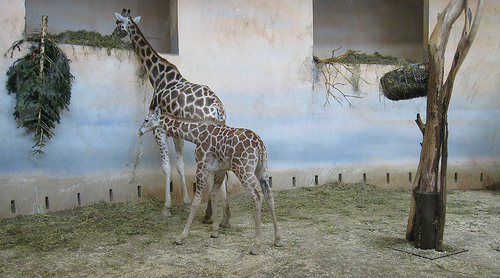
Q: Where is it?
A: This is at the zoo.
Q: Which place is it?
A: It is a zoo.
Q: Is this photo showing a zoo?
A: Yes, it is showing a zoo.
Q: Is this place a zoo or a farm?
A: It is a zoo.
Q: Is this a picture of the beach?
A: No, the picture is showing the zoo.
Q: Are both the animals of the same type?
A: Yes, all the animals are giraffes.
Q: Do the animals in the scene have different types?
A: No, all the animals are giraffes.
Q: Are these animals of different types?
A: No, all the animals are giraffes.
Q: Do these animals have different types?
A: No, all the animals are giraffes.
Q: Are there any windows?
A: Yes, there is a window.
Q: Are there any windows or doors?
A: Yes, there is a window.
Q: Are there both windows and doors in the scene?
A: No, there is a window but no doors.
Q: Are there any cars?
A: No, there are no cars.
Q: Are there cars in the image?
A: No, there are no cars.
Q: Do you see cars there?
A: No, there are no cars.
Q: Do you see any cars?
A: No, there are no cars.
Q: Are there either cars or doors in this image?
A: No, there are no cars or doors.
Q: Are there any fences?
A: No, there are no fences.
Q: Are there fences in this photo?
A: No, there are no fences.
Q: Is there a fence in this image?
A: No, there are no fences.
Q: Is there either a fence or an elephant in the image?
A: No, there are no fences or elephants.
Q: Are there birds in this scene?
A: No, there are no birds.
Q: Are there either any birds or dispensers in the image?
A: No, there are no birds or dispensers.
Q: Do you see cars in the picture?
A: No, there are no cars.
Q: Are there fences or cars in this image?
A: No, there are no cars or fences.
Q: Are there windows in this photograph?
A: Yes, there is a window.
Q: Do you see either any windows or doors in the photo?
A: Yes, there is a window.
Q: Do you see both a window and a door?
A: No, there is a window but no doors.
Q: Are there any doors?
A: No, there are no doors.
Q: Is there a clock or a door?
A: No, there are no doors or clocks.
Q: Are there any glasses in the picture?
A: No, there are no glasses.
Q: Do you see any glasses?
A: No, there are no glasses.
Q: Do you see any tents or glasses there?
A: No, there are no glasses or tents.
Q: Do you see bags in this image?
A: No, there are no bags.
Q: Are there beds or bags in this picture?
A: No, there are no bags or beds.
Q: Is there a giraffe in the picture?
A: Yes, there is a giraffe.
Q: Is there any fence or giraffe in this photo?
A: Yes, there is a giraffe.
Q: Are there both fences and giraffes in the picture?
A: No, there is a giraffe but no fences.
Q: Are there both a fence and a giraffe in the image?
A: No, there is a giraffe but no fences.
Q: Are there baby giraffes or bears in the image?
A: Yes, there is a baby giraffe.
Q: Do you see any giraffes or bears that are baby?
A: Yes, the giraffe is a baby.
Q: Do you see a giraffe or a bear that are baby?
A: Yes, the giraffe is a baby.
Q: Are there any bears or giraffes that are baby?
A: Yes, the giraffe is a baby.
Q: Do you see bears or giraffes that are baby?
A: Yes, the giraffe is a baby.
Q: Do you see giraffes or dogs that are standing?
A: Yes, the giraffe is standing.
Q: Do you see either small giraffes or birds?
A: Yes, there is a small giraffe.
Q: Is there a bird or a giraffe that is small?
A: Yes, the giraffe is small.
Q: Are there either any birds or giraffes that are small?
A: Yes, the giraffe is small.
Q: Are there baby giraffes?
A: Yes, there is a baby giraffe.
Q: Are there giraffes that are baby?
A: Yes, there is a giraffe that is a baby.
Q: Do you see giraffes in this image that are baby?
A: Yes, there is a giraffe that is a baby.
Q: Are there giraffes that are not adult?
A: Yes, there is an baby giraffe.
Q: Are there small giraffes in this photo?
A: Yes, there is a small giraffe.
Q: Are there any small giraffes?
A: Yes, there is a small giraffe.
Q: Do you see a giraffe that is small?
A: Yes, there is a giraffe that is small.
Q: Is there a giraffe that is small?
A: Yes, there is a giraffe that is small.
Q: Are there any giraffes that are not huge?
A: Yes, there is a small giraffe.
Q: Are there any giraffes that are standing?
A: Yes, there is a giraffe that is standing.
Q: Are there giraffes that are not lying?
A: Yes, there is a giraffe that is standing.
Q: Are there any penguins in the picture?
A: No, there are no penguins.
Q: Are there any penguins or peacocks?
A: No, there are no penguins or peacocks.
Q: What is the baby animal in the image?
A: The animal is a giraffe.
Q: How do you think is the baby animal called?
A: The animal is a giraffe.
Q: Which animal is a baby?
A: The animal is a giraffe.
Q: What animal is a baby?
A: The animal is a giraffe.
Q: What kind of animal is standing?
A: The animal is a giraffe.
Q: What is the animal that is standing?
A: The animal is a giraffe.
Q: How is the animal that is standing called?
A: The animal is a giraffe.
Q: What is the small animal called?
A: The animal is a giraffe.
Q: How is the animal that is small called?
A: The animal is a giraffe.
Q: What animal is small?
A: The animal is a giraffe.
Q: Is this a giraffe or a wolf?
A: This is a giraffe.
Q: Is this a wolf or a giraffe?
A: This is a giraffe.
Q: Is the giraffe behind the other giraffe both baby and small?
A: Yes, the giraffe is a baby and small.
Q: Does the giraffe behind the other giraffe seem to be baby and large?
A: No, the giraffe is a baby but small.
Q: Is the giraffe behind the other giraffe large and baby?
A: No, the giraffe is a baby but small.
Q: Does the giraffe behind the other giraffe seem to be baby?
A: Yes, the giraffe is a baby.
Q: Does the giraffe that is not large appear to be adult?
A: No, the giraffe is a baby.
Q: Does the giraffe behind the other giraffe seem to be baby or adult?
A: The giraffe is a baby.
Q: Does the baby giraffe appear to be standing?
A: Yes, the giraffe is standing.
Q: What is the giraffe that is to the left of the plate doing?
A: The giraffe is standing.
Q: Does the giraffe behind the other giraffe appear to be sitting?
A: No, the giraffe is standing.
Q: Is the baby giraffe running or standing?
A: The giraffe is standing.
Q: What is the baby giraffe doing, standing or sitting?
A: The giraffe is standing.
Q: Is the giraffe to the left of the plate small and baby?
A: Yes, the giraffe is small and baby.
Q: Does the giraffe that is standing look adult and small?
A: No, the giraffe is small but baby.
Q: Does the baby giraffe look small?
A: Yes, the giraffe is small.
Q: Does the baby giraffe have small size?
A: Yes, the giraffe is small.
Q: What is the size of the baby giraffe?
A: The giraffe is small.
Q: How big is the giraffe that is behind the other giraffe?
A: The giraffe is small.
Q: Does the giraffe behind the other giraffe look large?
A: No, the giraffe is small.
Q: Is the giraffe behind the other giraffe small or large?
A: The giraffe is small.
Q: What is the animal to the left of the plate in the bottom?
A: The animal is a giraffe.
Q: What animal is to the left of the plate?
A: The animal is a giraffe.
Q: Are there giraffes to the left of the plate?
A: Yes, there is a giraffe to the left of the plate.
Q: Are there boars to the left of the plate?
A: No, there is a giraffe to the left of the plate.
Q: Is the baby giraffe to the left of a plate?
A: Yes, the giraffe is to the left of a plate.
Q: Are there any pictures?
A: No, there are no pictures.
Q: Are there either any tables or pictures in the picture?
A: No, there are no pictures or tables.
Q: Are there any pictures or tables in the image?
A: No, there are no pictures or tables.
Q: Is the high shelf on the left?
A: Yes, the shelf is on the left of the image.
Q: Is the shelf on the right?
A: No, the shelf is on the left of the image.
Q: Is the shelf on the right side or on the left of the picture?
A: The shelf is on the left of the image.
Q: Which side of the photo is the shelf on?
A: The shelf is on the left of the image.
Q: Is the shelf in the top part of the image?
A: Yes, the shelf is in the top of the image.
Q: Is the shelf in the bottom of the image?
A: No, the shelf is in the top of the image.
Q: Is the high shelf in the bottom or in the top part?
A: The shelf is in the top of the image.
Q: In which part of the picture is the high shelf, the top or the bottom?
A: The shelf is in the top of the image.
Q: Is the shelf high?
A: Yes, the shelf is high.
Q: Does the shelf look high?
A: Yes, the shelf is high.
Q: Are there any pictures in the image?
A: No, there are no pictures.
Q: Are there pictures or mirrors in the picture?
A: No, there are no pictures or mirrors.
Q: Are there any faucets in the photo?
A: No, there are no faucets.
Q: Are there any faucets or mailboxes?
A: No, there are no faucets or mailboxes.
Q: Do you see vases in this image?
A: No, there are no vases.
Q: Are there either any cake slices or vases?
A: No, there are no vases or cake slices.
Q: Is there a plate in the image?
A: Yes, there is a plate.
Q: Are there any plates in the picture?
A: Yes, there is a plate.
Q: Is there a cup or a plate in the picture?
A: Yes, there is a plate.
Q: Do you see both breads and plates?
A: No, there is a plate but no breads.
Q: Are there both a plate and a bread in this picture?
A: No, there is a plate but no breads.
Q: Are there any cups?
A: No, there are no cups.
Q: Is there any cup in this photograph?
A: No, there are no cups.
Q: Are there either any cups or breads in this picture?
A: No, there are no cups or breads.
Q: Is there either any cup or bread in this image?
A: No, there are no cups or breads.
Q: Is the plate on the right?
A: Yes, the plate is on the right of the image.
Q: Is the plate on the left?
A: No, the plate is on the right of the image.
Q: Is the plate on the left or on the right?
A: The plate is on the right of the image.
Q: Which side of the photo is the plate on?
A: The plate is on the right of the image.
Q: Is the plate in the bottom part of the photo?
A: Yes, the plate is in the bottom of the image.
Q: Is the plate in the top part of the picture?
A: No, the plate is in the bottom of the image.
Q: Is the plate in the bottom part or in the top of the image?
A: The plate is in the bottom of the image.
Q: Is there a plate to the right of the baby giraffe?
A: Yes, there is a plate to the right of the giraffe.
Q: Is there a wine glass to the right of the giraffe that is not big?
A: No, there is a plate to the right of the giraffe.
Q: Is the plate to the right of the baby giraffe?
A: Yes, the plate is to the right of the giraffe.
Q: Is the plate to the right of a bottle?
A: No, the plate is to the right of the giraffe.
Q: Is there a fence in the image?
A: No, there are no fences.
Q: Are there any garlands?
A: No, there are no garlands.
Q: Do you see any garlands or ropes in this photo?
A: No, there are no garlands or ropes.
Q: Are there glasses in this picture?
A: No, there are no glasses.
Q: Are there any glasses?
A: No, there are no glasses.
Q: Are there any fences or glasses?
A: No, there are no glasses or fences.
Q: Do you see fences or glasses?
A: No, there are no glasses or fences.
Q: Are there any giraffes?
A: Yes, there is a giraffe.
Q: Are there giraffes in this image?
A: Yes, there is a giraffe.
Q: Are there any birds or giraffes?
A: Yes, there is a giraffe.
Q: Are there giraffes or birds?
A: Yes, there is a giraffe.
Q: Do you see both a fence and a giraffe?
A: No, there is a giraffe but no fences.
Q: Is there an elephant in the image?
A: No, there are no elephants.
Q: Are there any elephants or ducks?
A: No, there are no elephants or ducks.